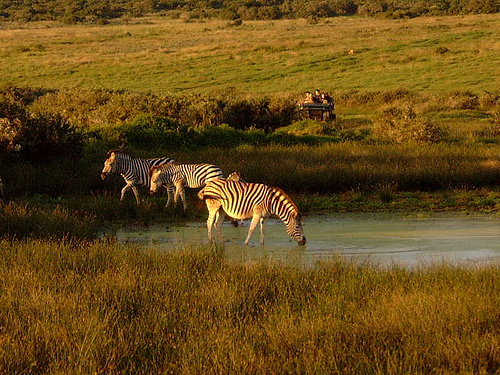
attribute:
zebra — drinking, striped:
[196, 178, 307, 253]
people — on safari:
[300, 89, 334, 106]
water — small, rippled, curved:
[102, 214, 500, 290]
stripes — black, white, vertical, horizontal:
[211, 179, 286, 218]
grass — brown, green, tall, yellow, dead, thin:
[6, 31, 497, 86]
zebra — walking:
[98, 151, 230, 207]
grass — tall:
[1, 190, 498, 240]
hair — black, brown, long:
[275, 187, 301, 218]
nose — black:
[296, 238, 307, 247]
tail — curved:
[197, 187, 221, 202]